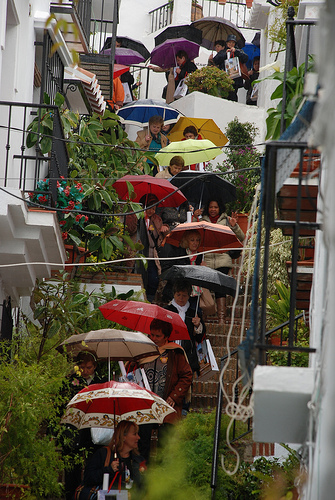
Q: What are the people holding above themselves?
A: Umbrella.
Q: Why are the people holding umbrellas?
A: It's raining.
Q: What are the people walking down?
A: Brick stairs.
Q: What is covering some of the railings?
A: Plants and flowers.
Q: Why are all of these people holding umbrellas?
A: To stay dry.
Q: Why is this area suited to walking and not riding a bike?
A: Because of the stairs.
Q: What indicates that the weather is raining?
A: Everyone is holding umbrellas.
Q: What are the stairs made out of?
A: Brick.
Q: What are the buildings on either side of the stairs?
A: Apartments.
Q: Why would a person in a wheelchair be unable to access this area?
A: Because of the stairs.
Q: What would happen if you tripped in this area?
A: You would get badly hurt.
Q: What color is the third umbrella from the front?
A: Red.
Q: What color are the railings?
A: Black.